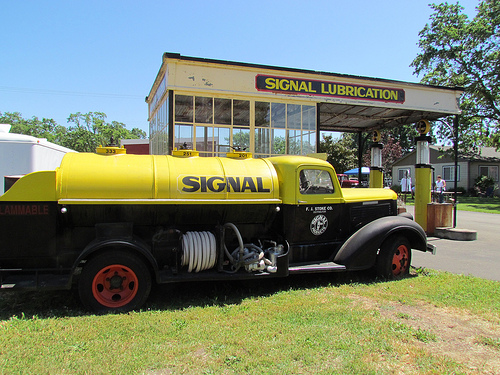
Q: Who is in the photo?
A: Person in white shirt.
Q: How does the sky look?
A: Blue.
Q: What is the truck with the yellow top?
A: Black.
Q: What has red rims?
A: Truck.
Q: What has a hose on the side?
A: The truck.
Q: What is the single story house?
A: Brown.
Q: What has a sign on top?
A: The store.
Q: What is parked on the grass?
A: The truck.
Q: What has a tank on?
A: An old truck.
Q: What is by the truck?
A: Patch of grass.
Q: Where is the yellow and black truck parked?
A: In the grass.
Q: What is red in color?
A: Rims on the tires.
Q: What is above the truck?
A: A clear blue sky.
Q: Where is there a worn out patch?
A: In the grass.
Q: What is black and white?
A: Truck.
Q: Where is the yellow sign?
A: On building.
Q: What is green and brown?
A: The ground.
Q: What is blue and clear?
A: The sky.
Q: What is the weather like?
A: Clear.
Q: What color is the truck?
A: Black and yellow.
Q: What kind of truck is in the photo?
A: Gas truck.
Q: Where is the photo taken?
A: Daytime.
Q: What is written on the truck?
A: Signal.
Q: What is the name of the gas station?
A: Signal lubrication.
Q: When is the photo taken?
A: White.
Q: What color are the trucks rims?
A: Red.